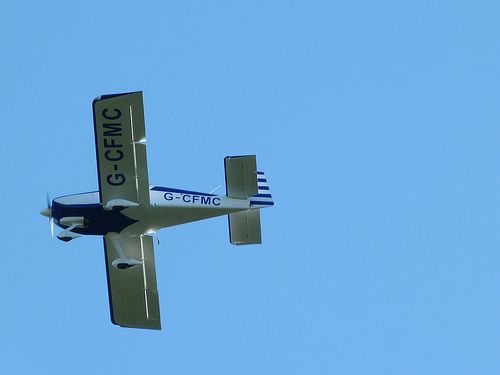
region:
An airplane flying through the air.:
[29, 66, 295, 351]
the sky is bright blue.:
[339, 197, 431, 261]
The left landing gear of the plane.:
[108, 240, 144, 274]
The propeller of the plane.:
[33, 193, 54, 235]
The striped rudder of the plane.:
[257, 166, 272, 212]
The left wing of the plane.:
[101, 244, 166, 340]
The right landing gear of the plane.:
[103, 195, 138, 215]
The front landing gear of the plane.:
[55, 217, 90, 244]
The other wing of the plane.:
[81, 90, 156, 202]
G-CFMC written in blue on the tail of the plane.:
[158, 186, 223, 212]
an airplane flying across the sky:
[17, 33, 377, 336]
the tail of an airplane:
[218, 143, 278, 254]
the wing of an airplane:
[85, 83, 166, 188]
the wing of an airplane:
[92, 238, 184, 333]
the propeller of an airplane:
[31, 181, 54, 248]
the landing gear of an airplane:
[99, 196, 144, 218]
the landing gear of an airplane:
[106, 238, 142, 275]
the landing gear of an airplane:
[58, 213, 88, 248]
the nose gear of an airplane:
[54, 212, 91, 244]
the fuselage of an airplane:
[75, 189, 223, 244]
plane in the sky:
[32, 80, 297, 360]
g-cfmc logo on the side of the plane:
[160, 184, 227, 216]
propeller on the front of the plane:
[34, 193, 57, 244]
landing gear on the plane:
[95, 197, 145, 279]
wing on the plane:
[103, 278, 167, 339]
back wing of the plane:
[212, 150, 261, 197]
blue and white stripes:
[258, 174, 274, 211]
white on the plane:
[60, 195, 96, 210]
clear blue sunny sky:
[308, 172, 401, 267]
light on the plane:
[133, 132, 148, 147]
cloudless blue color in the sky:
[295, 69, 407, 150]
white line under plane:
[133, 235, 149, 292]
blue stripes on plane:
[251, 173, 277, 206]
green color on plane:
[121, 290, 136, 310]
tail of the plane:
[213, 151, 285, 257]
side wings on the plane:
[88, 258, 178, 327]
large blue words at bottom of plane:
[95, 102, 146, 192]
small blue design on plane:
[110, 253, 150, 280]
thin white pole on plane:
[195, 176, 222, 194]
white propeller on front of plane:
[23, 187, 64, 254]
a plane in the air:
[34, 80, 285, 337]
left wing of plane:
[87, 85, 157, 192]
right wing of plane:
[99, 230, 168, 337]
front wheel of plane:
[51, 220, 84, 245]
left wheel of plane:
[99, 192, 145, 219]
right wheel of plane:
[109, 252, 145, 276]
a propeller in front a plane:
[36, 183, 58, 241]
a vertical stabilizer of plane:
[254, 165, 279, 212]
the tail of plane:
[217, 146, 279, 256]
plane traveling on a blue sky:
[16, 53, 316, 355]